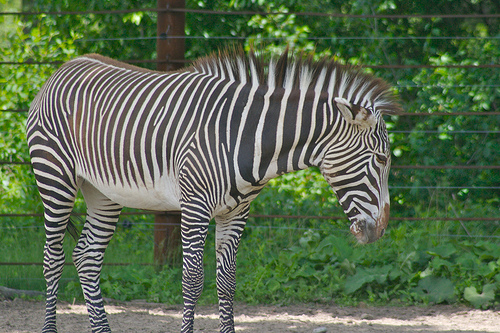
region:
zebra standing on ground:
[20, 20, 422, 331]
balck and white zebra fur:
[95, 89, 190, 152]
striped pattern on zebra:
[80, 85, 190, 152]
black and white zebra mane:
[190, 42, 418, 112]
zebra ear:
[325, 90, 376, 135]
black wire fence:
[3, 1, 498, 292]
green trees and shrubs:
[1, 0, 491, 322]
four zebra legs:
[27, 225, 260, 332]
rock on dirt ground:
[307, 318, 339, 331]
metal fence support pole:
[138, 0, 203, 274]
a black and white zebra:
[21, 41, 405, 331]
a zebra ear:
[334, 94, 371, 128]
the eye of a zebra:
[371, 150, 388, 165]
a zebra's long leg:
[175, 205, 205, 331]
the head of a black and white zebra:
[312, 60, 404, 248]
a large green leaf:
[461, 280, 498, 308]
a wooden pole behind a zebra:
[153, 1, 181, 276]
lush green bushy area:
[396, 27, 499, 301]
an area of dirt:
[256, 305, 498, 332]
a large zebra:
[18, 49, 409, 331]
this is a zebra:
[8, 38, 397, 332]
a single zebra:
[16, 27, 425, 329]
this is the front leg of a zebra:
[168, 189, 263, 330]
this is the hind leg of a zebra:
[15, 59, 126, 331]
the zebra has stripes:
[13, 30, 408, 331]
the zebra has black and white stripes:
[17, 33, 407, 331]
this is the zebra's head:
[312, 60, 419, 257]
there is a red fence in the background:
[0, 0, 497, 267]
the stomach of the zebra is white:
[56, 151, 248, 224]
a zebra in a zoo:
[26, 35, 410, 329]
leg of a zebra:
[178, 209, 203, 329]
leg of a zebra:
[212, 218, 243, 328]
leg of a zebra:
[20, 150, 70, 331]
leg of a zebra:
[67, 195, 114, 331]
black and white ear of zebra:
[326, 85, 376, 139]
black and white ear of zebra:
[326, 80, 380, 131]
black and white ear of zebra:
[324, 86, 389, 140]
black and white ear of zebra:
[326, 73, 400, 145]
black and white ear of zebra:
[326, 83, 393, 133]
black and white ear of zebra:
[321, 85, 392, 135]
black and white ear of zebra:
[316, 75, 401, 145]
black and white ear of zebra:
[326, 91, 395, 147]